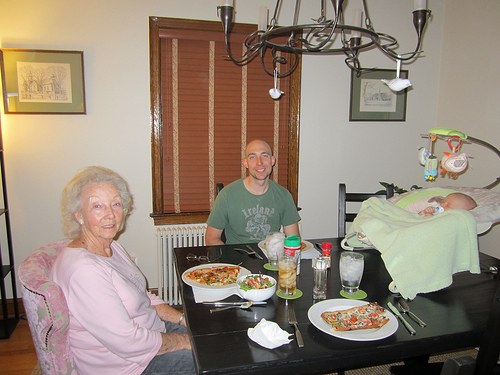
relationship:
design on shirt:
[244, 200, 284, 239] [200, 185, 306, 248]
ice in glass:
[335, 253, 363, 276] [302, 249, 359, 303]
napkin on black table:
[244, 315, 297, 352] [165, 235, 499, 375]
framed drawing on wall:
[347, 63, 409, 124] [4, 5, 498, 299]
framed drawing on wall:
[2, 43, 87, 115] [4, 5, 498, 299]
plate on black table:
[182, 262, 252, 292] [165, 235, 499, 375]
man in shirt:
[206, 134, 301, 251] [205, 175, 297, 243]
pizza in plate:
[321, 305, 383, 330] [258, 235, 315, 253]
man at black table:
[206, 134, 301, 251] [165, 235, 499, 375]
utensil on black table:
[204, 297, 276, 317] [165, 235, 499, 375]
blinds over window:
[147, 16, 305, 217] [121, 16, 334, 228]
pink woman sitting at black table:
[48, 167, 198, 375] [165, 235, 499, 375]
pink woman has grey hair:
[48, 167, 198, 375] [58, 164, 131, 239]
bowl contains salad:
[235, 272, 277, 302] [245, 274, 269, 288]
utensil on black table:
[232, 247, 254, 262] [165, 235, 499, 375]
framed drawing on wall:
[2, 48, 88, 115] [4, 5, 498, 299]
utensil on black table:
[280, 302, 306, 352] [165, 235, 499, 375]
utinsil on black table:
[388, 302, 415, 337] [165, 235, 498, 368]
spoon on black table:
[397, 297, 426, 327] [165, 235, 498, 368]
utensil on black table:
[280, 302, 306, 352] [165, 235, 498, 368]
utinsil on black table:
[214, 300, 253, 315] [165, 235, 498, 368]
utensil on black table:
[204, 297, 276, 317] [165, 235, 498, 368]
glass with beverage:
[278, 255, 298, 295] [274, 260, 296, 292]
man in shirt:
[206, 134, 301, 251] [198, 177, 308, 244]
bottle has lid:
[281, 226, 305, 281] [283, 233, 303, 252]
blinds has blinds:
[147, 16, 305, 217] [161, 32, 253, 155]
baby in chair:
[376, 185, 493, 234] [347, 120, 498, 278]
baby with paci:
[376, 185, 493, 234] [425, 191, 443, 204]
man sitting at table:
[222, 134, 299, 249] [205, 235, 270, 274]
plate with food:
[182, 262, 252, 292] [189, 263, 240, 285]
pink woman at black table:
[48, 167, 198, 375] [165, 235, 499, 375]